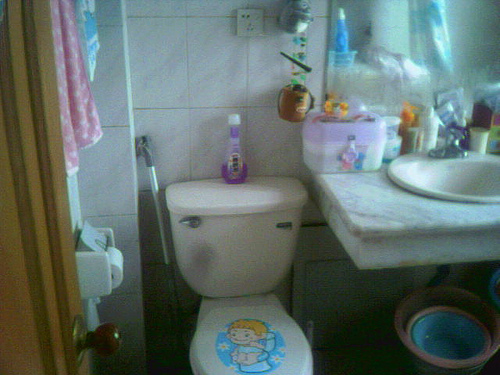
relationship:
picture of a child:
[212, 316, 289, 375] [226, 318, 276, 373]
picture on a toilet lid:
[212, 316, 289, 375] [188, 302, 320, 374]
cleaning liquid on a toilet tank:
[219, 110, 250, 187] [162, 172, 311, 299]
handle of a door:
[66, 315, 125, 364] [0, 1, 100, 374]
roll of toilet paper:
[102, 242, 128, 293] [103, 239, 128, 297]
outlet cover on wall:
[231, 7, 266, 41] [128, 2, 499, 371]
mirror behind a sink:
[324, 2, 496, 131] [384, 145, 499, 211]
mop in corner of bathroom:
[140, 130, 191, 374] [4, 0, 500, 373]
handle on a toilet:
[175, 217, 203, 231] [160, 174, 320, 374]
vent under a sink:
[291, 222, 413, 375] [384, 145, 499, 211]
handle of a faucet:
[445, 127, 467, 141] [424, 124, 472, 161]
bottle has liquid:
[219, 109, 251, 189] [223, 161, 248, 186]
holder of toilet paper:
[74, 224, 118, 305] [103, 239, 128, 297]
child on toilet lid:
[226, 318, 276, 373] [188, 302, 320, 374]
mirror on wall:
[324, 2, 496, 131] [128, 2, 499, 371]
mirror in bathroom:
[324, 2, 496, 131] [4, 0, 500, 373]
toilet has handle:
[160, 174, 320, 374] [175, 217, 203, 231]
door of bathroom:
[0, 1, 100, 374] [4, 0, 500, 373]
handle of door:
[66, 315, 125, 364] [0, 1, 100, 374]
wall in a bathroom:
[128, 2, 499, 371] [4, 0, 500, 373]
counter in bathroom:
[304, 155, 499, 269] [4, 0, 500, 373]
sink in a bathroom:
[384, 145, 499, 211] [4, 0, 500, 373]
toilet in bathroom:
[160, 174, 320, 374] [4, 0, 500, 373]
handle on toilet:
[175, 217, 203, 231] [160, 174, 320, 374]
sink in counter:
[384, 145, 499, 211] [304, 155, 499, 269]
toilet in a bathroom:
[160, 174, 320, 374] [4, 0, 500, 373]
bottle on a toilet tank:
[219, 109, 251, 189] [162, 172, 311, 299]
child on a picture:
[226, 318, 276, 373] [212, 316, 289, 375]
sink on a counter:
[384, 145, 499, 211] [304, 155, 499, 269]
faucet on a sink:
[424, 124, 472, 161] [384, 145, 499, 211]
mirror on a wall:
[324, 2, 496, 131] [128, 2, 499, 371]